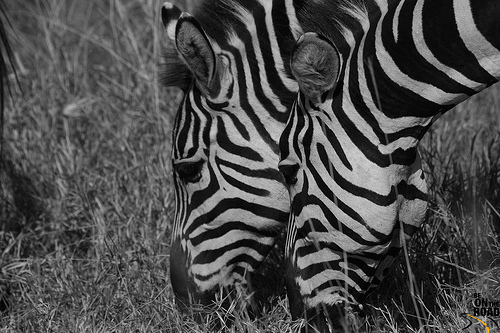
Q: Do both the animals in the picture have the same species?
A: Yes, all the animals are zebras.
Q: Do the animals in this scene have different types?
A: No, all the animals are zebras.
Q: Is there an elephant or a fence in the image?
A: No, there are no fences or elephants.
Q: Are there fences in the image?
A: No, there are no fences.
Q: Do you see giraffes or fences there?
A: No, there are no fences or giraffes.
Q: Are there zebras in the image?
A: Yes, there is a zebra.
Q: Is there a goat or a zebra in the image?
A: Yes, there is a zebra.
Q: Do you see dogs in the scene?
A: No, there are no dogs.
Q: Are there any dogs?
A: No, there are no dogs.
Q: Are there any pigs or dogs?
A: No, there are no dogs or pigs.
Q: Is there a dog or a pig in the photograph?
A: No, there are no dogs or pigs.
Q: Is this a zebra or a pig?
A: This is a zebra.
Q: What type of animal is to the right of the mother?
A: The animal is a zebra.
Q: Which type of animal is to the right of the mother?
A: The animal is a zebra.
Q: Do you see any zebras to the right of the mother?
A: Yes, there is a zebra to the right of the mother.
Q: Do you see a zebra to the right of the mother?
A: Yes, there is a zebra to the right of the mother.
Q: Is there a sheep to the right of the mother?
A: No, there is a zebra to the right of the mother.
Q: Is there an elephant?
A: No, there are no elephants.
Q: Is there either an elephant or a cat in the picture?
A: No, there are no elephants or cats.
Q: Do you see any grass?
A: Yes, there is grass.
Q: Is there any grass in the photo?
A: Yes, there is grass.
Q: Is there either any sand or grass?
A: Yes, there is grass.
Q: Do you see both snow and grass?
A: No, there is grass but no snow.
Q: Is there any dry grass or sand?
A: Yes, there is dry grass.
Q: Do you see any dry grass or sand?
A: Yes, there is dry grass.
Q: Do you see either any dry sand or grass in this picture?
A: Yes, there is dry grass.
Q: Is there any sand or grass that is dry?
A: Yes, the grass is dry.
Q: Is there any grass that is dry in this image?
A: Yes, there is dry grass.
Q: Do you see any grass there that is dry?
A: Yes, there is grass that is dry.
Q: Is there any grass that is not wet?
A: Yes, there is dry grass.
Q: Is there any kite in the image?
A: No, there are no kites.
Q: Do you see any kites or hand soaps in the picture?
A: No, there are no kites or hand soaps.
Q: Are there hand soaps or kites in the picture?
A: No, there are no kites or hand soaps.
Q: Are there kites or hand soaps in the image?
A: No, there are no kites or hand soaps.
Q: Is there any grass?
A: Yes, there is grass.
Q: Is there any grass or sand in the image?
A: Yes, there is grass.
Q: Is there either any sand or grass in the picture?
A: Yes, there is grass.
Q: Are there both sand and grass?
A: No, there is grass but no sand.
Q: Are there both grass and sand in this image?
A: No, there is grass but no sand.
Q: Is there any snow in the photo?
A: No, there is no snow.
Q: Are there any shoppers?
A: No, there are no shoppers.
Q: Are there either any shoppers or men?
A: No, there are no shoppers or men.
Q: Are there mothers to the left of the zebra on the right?
A: Yes, there is a mother to the left of the zebra.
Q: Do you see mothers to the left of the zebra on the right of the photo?
A: Yes, there is a mother to the left of the zebra.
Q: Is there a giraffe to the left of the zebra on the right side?
A: No, there is a mother to the left of the zebra.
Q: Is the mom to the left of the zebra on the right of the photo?
A: Yes, the mom is to the left of the zebra.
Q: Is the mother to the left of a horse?
A: No, the mother is to the left of the zebra.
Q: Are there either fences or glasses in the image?
A: No, there are no fences or glasses.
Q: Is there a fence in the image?
A: No, there are no fences.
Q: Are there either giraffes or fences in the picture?
A: No, there are no fences or giraffes.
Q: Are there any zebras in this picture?
A: Yes, there is a zebra.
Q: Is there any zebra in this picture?
A: Yes, there is a zebra.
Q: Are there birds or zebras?
A: Yes, there is a zebra.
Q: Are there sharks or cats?
A: No, there are no cats or sharks.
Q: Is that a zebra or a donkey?
A: That is a zebra.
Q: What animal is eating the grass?
A: The zebra is eating the grass.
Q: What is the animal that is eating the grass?
A: The animal is a zebra.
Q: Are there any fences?
A: No, there are no fences.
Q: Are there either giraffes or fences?
A: No, there are no fences or giraffes.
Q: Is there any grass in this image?
A: Yes, there is grass.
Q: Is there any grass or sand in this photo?
A: Yes, there is grass.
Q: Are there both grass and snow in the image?
A: No, there is grass but no snow.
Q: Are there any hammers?
A: No, there are no hammers.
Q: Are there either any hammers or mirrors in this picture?
A: No, there are no hammers or mirrors.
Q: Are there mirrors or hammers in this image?
A: No, there are no hammers or mirrors.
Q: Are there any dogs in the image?
A: No, there are no dogs.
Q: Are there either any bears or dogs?
A: No, there are no dogs or bears.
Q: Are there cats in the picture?
A: No, there are no cats.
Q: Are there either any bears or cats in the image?
A: No, there are no cats or bears.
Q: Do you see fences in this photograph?
A: No, there are no fences.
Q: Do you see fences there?
A: No, there are no fences.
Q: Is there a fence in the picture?
A: No, there are no fences.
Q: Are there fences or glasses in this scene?
A: No, there are no fences or glasses.